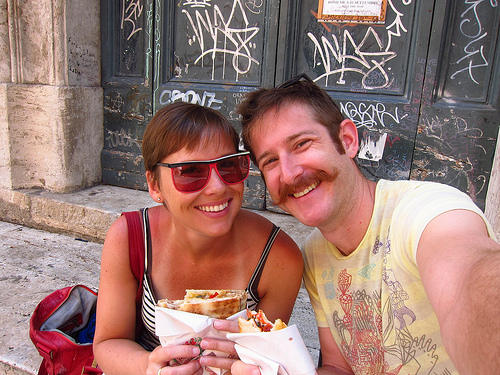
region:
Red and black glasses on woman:
[157, 149, 254, 197]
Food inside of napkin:
[152, 288, 252, 322]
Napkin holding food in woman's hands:
[146, 307, 246, 374]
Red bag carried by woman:
[21, 281, 122, 373]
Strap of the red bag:
[113, 204, 150, 301]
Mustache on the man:
[272, 163, 342, 211]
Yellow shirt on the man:
[292, 173, 498, 373]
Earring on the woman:
[155, 194, 163, 206]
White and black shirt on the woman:
[128, 204, 283, 340]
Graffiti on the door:
[111, 0, 498, 138]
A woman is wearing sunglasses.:
[152, 150, 252, 193]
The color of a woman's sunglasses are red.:
[153, 150, 250, 193]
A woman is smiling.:
[142, 101, 246, 239]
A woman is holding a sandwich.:
[150, 288, 247, 373]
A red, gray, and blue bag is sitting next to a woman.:
[25, 283, 100, 374]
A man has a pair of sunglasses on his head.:
[234, 72, 320, 118]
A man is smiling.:
[235, 74, 360, 226]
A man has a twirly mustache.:
[261, 164, 339, 210]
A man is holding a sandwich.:
[195, 304, 325, 374]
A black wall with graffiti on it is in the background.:
[97, 0, 499, 215]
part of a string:
[243, 229, 270, 304]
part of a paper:
[265, 323, 281, 346]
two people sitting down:
[96, 71, 498, 373]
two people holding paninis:
[150, 281, 318, 372]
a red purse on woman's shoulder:
[30, 206, 150, 371]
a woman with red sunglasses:
[152, 150, 252, 191]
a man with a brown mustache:
[263, 168, 345, 208]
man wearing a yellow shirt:
[298, 180, 495, 374]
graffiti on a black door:
[101, 0, 496, 212]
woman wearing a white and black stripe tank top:
[136, 208, 283, 348]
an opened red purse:
[28, 282, 97, 374]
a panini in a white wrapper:
[152, 284, 249, 374]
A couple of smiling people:
[91, 79, 497, 373]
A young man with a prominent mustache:
[239, 78, 495, 373]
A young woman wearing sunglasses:
[94, 104, 299, 373]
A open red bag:
[29, 283, 97, 373]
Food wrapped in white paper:
[158, 290, 247, 365]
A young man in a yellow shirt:
[242, 77, 495, 373]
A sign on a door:
[314, 0, 388, 23]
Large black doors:
[94, 1, 499, 211]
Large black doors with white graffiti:
[104, 0, 494, 218]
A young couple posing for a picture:
[94, 77, 496, 373]